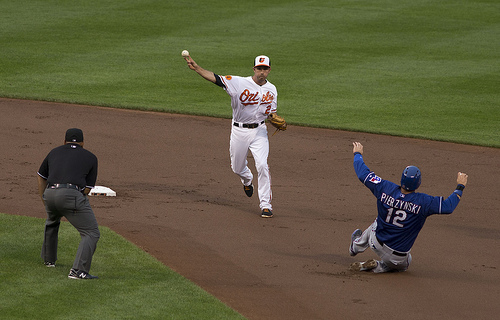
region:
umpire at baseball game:
[33, 127, 103, 285]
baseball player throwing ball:
[173, 43, 293, 221]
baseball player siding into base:
[330, 135, 472, 277]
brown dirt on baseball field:
[135, 126, 222, 241]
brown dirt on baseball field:
[211, 225, 336, 295]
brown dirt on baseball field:
[98, 117, 219, 177]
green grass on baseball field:
[14, 6, 165, 92]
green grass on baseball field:
[293, 12, 488, 122]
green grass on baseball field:
[20, 285, 170, 317]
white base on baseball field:
[100, 180, 117, 205]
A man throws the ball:
[176, 48, 290, 224]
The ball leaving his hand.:
[175, 43, 198, 72]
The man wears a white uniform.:
[211, 66, 287, 208]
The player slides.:
[345, 125, 473, 297]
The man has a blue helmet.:
[393, 158, 429, 195]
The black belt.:
[230, 119, 269, 131]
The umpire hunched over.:
[25, 112, 114, 288]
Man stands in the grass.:
[26, 110, 107, 291]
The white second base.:
[85, 181, 122, 203]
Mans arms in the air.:
[347, 131, 474, 216]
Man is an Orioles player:
[181, 46, 289, 219]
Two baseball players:
[177, 40, 472, 275]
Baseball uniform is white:
[214, 75, 281, 214]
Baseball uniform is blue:
[353, 152, 465, 247]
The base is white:
[89, 184, 115, 197]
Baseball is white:
[182, 47, 189, 59]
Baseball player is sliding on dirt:
[347, 140, 467, 273]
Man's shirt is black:
[41, 146, 96, 189]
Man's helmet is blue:
[402, 166, 422, 189]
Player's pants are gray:
[355, 218, 414, 272]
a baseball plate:
[92, 174, 125, 196]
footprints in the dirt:
[5, 96, 54, 220]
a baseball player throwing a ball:
[163, 37, 321, 220]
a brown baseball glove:
[267, 102, 284, 134]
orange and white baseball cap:
[248, 47, 278, 68]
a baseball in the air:
[178, 46, 193, 61]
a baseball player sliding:
[337, 128, 470, 277]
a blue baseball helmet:
[393, 160, 433, 191]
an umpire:
[38, 122, 106, 279]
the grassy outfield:
[12, 1, 492, 141]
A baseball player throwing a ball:
[174, 33, 321, 225]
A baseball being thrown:
[178, 45, 193, 61]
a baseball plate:
[86, 182, 126, 204]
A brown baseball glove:
[260, 105, 291, 140]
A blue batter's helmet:
[390, 158, 428, 189]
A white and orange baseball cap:
[247, 47, 272, 72]